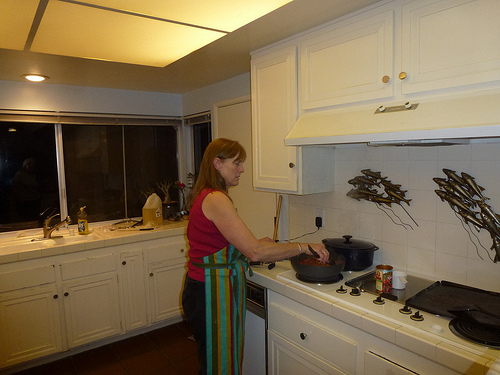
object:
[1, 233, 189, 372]
cabinet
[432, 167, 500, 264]
fish sculpture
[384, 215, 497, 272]
wall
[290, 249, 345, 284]
skillet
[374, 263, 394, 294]
can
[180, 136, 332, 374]
woman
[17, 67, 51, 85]
light fixture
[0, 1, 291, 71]
light fixture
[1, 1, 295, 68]
ceiling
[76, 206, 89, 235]
bottle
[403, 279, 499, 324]
cookie sheet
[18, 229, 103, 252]
kitchen sink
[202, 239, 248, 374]
apron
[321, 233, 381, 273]
pot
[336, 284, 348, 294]
knob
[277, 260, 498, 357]
stove top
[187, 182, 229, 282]
shirt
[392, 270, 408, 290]
cup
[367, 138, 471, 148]
vent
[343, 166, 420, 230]
fish sculpture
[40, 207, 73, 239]
faucet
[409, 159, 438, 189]
tile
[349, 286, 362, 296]
knob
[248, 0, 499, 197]
cabinet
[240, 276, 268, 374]
dishwasher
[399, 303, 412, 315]
knob